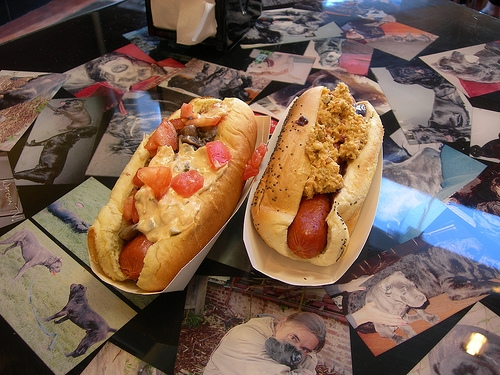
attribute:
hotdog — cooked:
[148, 106, 223, 264]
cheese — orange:
[141, 208, 186, 236]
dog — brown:
[19, 224, 59, 296]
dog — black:
[72, 281, 102, 365]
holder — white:
[235, 233, 301, 307]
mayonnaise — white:
[205, 105, 227, 107]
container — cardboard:
[249, 116, 293, 295]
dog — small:
[370, 279, 424, 341]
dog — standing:
[62, 284, 93, 357]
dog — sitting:
[309, 44, 358, 79]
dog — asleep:
[429, 248, 499, 296]